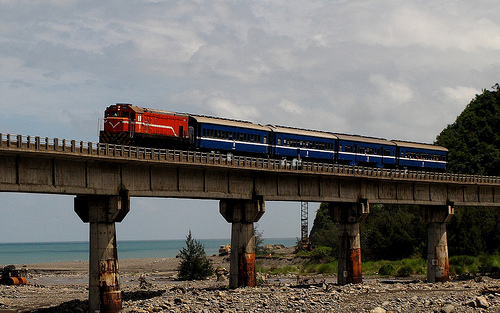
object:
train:
[96, 102, 450, 177]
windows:
[276, 134, 335, 151]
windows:
[336, 141, 393, 158]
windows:
[397, 146, 449, 162]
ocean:
[2, 237, 322, 263]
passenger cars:
[267, 123, 335, 163]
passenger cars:
[334, 130, 398, 170]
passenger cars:
[390, 139, 447, 173]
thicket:
[359, 114, 498, 259]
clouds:
[0, 0, 500, 145]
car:
[185, 113, 274, 159]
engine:
[97, 103, 187, 153]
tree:
[174, 230, 218, 282]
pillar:
[229, 219, 256, 288]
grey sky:
[1, 0, 498, 241]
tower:
[299, 200, 309, 252]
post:
[329, 201, 370, 287]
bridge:
[0, 132, 499, 312]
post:
[75, 196, 132, 311]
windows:
[203, 123, 261, 144]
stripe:
[200, 133, 450, 165]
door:
[177, 120, 186, 137]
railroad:
[0, 132, 500, 183]